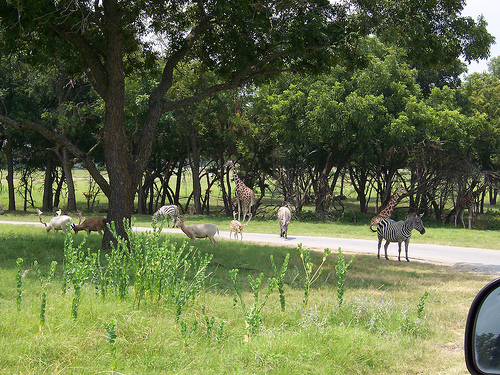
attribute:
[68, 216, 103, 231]
elk — white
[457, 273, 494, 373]
mirror — black, dark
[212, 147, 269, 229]
giraffe — laying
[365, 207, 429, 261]
animal — types, different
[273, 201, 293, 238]
animal — crossing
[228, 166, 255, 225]
giraffe — standing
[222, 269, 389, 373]
flowers — lavender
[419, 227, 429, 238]
snout — black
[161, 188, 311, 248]
elk — white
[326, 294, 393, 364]
grass — green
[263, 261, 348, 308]
plants — little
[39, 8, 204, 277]
tree — tall